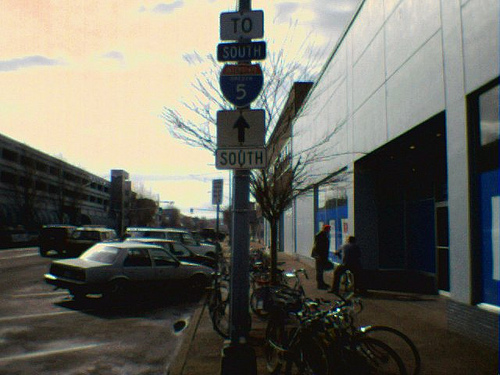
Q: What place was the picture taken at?
A: It was taken at the street.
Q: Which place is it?
A: It is a street.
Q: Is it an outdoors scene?
A: Yes, it is outdoors.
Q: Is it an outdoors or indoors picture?
A: It is outdoors.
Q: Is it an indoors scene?
A: No, it is outdoors.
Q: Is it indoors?
A: No, it is outdoors.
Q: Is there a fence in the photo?
A: No, there are no fences.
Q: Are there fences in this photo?
A: No, there are no fences.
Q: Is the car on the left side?
A: Yes, the car is on the left of the image.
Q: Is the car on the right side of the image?
A: No, the car is on the left of the image.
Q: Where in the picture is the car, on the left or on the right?
A: The car is on the left of the image.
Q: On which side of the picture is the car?
A: The car is on the left of the image.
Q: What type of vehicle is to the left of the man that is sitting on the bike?
A: The vehicle is a car.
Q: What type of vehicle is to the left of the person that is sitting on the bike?
A: The vehicle is a car.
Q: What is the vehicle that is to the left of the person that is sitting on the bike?
A: The vehicle is a car.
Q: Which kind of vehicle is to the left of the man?
A: The vehicle is a car.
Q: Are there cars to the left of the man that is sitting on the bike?
A: Yes, there is a car to the left of the man.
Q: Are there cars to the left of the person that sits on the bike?
A: Yes, there is a car to the left of the man.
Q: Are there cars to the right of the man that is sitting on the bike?
A: No, the car is to the left of the man.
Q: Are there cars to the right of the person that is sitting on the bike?
A: No, the car is to the left of the man.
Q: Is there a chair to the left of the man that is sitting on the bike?
A: No, there is a car to the left of the man.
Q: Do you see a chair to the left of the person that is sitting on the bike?
A: No, there is a car to the left of the man.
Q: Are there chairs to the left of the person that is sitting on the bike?
A: No, there is a car to the left of the man.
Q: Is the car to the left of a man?
A: Yes, the car is to the left of a man.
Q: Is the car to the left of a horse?
A: No, the car is to the left of a man.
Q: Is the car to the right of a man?
A: No, the car is to the left of a man.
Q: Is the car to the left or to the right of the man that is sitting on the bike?
A: The car is to the left of the man.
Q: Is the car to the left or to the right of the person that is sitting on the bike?
A: The car is to the left of the man.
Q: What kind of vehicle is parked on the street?
A: The vehicle is a car.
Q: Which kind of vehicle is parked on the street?
A: The vehicle is a car.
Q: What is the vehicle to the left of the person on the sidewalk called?
A: The vehicle is a car.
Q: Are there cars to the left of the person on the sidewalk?
A: Yes, there is a car to the left of the person.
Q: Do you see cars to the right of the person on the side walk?
A: No, the car is to the left of the person.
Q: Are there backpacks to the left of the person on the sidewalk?
A: No, there is a car to the left of the person.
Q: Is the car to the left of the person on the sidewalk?
A: Yes, the car is to the left of the person.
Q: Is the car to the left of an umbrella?
A: No, the car is to the left of the person.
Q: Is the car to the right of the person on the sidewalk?
A: No, the car is to the left of the person.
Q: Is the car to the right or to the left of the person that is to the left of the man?
A: The car is to the left of the person.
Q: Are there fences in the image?
A: No, there are no fences.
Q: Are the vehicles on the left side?
A: Yes, the vehicles are on the left of the image.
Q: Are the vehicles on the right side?
A: No, the vehicles are on the left of the image.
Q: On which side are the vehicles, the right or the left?
A: The vehicles are on the left of the image.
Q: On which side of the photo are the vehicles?
A: The vehicles are on the left of the image.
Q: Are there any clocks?
A: No, there are no clocks.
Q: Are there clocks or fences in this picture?
A: No, there are no clocks or fences.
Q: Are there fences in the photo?
A: No, there are no fences.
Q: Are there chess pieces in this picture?
A: No, there are no chess pieces.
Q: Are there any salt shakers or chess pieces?
A: No, there are no chess pieces or salt shakers.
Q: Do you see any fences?
A: No, there are no fences.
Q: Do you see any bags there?
A: No, there are no bags.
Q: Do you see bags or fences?
A: No, there are no bags or fences.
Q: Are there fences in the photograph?
A: No, there are no fences.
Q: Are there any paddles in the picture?
A: No, there are no paddles.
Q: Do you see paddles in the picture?
A: No, there are no paddles.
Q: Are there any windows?
A: Yes, there is a window.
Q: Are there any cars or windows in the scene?
A: Yes, there is a window.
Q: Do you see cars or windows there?
A: Yes, there is a window.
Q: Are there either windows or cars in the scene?
A: Yes, there is a window.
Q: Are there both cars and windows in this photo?
A: Yes, there are both a window and a car.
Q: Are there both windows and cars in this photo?
A: Yes, there are both a window and a car.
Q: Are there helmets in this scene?
A: No, there are no helmets.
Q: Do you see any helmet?
A: No, there are no helmets.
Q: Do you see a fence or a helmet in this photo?
A: No, there are no helmets or fences.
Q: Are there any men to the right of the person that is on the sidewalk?
A: Yes, there is a man to the right of the person.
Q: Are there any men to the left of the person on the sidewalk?
A: No, the man is to the right of the person.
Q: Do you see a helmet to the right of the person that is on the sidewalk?
A: No, there is a man to the right of the person.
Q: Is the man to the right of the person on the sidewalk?
A: Yes, the man is to the right of the person.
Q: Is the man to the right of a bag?
A: No, the man is to the right of the person.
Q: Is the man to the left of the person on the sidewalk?
A: No, the man is to the right of the person.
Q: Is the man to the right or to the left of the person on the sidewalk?
A: The man is to the right of the person.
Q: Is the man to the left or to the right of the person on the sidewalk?
A: The man is to the right of the person.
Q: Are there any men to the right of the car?
A: Yes, there is a man to the right of the car.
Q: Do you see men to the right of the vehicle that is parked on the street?
A: Yes, there is a man to the right of the car.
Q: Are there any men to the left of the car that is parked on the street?
A: No, the man is to the right of the car.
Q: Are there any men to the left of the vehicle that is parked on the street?
A: No, the man is to the right of the car.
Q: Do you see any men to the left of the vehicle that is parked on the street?
A: No, the man is to the right of the car.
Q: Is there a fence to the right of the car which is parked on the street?
A: No, there is a man to the right of the car.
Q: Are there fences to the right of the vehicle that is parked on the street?
A: No, there is a man to the right of the car.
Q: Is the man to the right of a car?
A: Yes, the man is to the right of a car.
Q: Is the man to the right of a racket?
A: No, the man is to the right of a car.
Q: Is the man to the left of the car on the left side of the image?
A: No, the man is to the right of the car.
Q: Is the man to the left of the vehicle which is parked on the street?
A: No, the man is to the right of the car.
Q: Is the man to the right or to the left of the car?
A: The man is to the right of the car.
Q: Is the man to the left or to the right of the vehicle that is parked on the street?
A: The man is to the right of the car.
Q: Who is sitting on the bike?
A: The man is sitting on the bike.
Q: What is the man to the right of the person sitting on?
A: The man is sitting on the bike.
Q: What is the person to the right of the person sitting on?
A: The man is sitting on the bike.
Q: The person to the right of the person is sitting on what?
A: The man is sitting on the bike.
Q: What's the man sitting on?
A: The man is sitting on the bike.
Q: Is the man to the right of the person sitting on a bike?
A: Yes, the man is sitting on a bike.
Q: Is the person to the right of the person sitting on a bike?
A: Yes, the man is sitting on a bike.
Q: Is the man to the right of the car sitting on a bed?
A: No, the man is sitting on a bike.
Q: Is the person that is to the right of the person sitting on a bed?
A: No, the man is sitting on a bike.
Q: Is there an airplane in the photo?
A: No, there are no airplanes.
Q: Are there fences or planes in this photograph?
A: No, there are no planes or fences.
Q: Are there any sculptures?
A: No, there are no sculptures.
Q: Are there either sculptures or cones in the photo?
A: No, there are no sculptures or cones.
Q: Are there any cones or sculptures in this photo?
A: No, there are no sculptures or cones.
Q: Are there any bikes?
A: Yes, there is a bike.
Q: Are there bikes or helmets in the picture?
A: Yes, there is a bike.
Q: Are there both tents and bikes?
A: No, there is a bike but no tents.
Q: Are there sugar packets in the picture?
A: No, there are no sugar packets.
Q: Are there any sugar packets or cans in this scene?
A: No, there are no sugar packets or cans.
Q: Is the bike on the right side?
A: Yes, the bike is on the right of the image.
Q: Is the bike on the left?
A: No, the bike is on the right of the image.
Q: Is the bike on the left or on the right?
A: The bike is on the right of the image.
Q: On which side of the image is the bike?
A: The bike is on the right of the image.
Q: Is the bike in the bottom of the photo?
A: Yes, the bike is in the bottom of the image.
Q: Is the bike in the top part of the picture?
A: No, the bike is in the bottom of the image.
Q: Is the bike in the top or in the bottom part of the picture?
A: The bike is in the bottom of the image.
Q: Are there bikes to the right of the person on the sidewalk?
A: Yes, there is a bike to the right of the person.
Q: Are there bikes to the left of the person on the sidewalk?
A: No, the bike is to the right of the person.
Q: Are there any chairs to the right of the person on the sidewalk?
A: No, there is a bike to the right of the person.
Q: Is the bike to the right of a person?
A: Yes, the bike is to the right of a person.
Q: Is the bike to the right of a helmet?
A: No, the bike is to the right of a person.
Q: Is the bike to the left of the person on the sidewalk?
A: No, the bike is to the right of the person.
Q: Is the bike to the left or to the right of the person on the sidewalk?
A: The bike is to the right of the person.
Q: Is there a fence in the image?
A: No, there are no fences.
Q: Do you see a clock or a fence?
A: No, there are no fences or clocks.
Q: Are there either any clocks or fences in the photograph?
A: No, there are no fences or clocks.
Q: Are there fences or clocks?
A: No, there are no fences or clocks.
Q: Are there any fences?
A: No, there are no fences.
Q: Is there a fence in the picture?
A: No, there are no fences.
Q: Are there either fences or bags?
A: No, there are no fences or bags.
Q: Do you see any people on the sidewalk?
A: Yes, there is a person on the sidewalk.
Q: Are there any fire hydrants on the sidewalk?
A: No, there is a person on the sidewalk.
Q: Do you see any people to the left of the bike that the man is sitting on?
A: Yes, there is a person to the left of the bike.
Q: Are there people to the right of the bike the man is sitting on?
A: No, the person is to the left of the bike.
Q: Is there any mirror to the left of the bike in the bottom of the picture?
A: No, there is a person to the left of the bike.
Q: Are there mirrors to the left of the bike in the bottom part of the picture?
A: No, there is a person to the left of the bike.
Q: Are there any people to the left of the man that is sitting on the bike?
A: Yes, there is a person to the left of the man.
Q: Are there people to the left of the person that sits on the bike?
A: Yes, there is a person to the left of the man.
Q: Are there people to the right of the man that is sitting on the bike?
A: No, the person is to the left of the man.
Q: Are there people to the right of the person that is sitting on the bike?
A: No, the person is to the left of the man.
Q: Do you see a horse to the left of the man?
A: No, there is a person to the left of the man.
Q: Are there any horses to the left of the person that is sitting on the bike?
A: No, there is a person to the left of the man.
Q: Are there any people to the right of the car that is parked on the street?
A: Yes, there is a person to the right of the car.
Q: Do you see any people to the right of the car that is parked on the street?
A: Yes, there is a person to the right of the car.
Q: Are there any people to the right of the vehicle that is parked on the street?
A: Yes, there is a person to the right of the car.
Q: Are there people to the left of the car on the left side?
A: No, the person is to the right of the car.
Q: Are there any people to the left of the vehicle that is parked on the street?
A: No, the person is to the right of the car.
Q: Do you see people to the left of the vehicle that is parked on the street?
A: No, the person is to the right of the car.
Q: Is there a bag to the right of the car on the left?
A: No, there is a person to the right of the car.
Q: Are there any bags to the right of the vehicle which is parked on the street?
A: No, there is a person to the right of the car.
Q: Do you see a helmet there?
A: No, there are no helmets.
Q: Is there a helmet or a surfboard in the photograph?
A: No, there are no helmets or surfboards.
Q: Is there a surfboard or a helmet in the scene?
A: No, there are no helmets or surfboards.